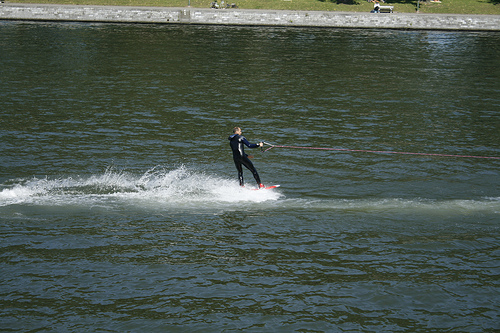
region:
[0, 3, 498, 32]
a wall built along the edge of the water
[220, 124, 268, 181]
man in a black wetsuit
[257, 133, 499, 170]
a red water ski rope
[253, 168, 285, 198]
a red ski board in the water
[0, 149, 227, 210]
the wake of water skiing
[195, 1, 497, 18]
grass on the edge of the water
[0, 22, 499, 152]
ripples in the water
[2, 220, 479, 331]
the sky reflects light on the water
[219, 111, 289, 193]
skiing with one hand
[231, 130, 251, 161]
the front of the wet suit has a shine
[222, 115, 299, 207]
Man wearing a wet suite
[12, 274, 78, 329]
Small ripples in the water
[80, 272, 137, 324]
Small ripples in the water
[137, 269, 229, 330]
Small ripples in the water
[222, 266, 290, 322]
Small ripples in the water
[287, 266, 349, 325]
Small ripples in the water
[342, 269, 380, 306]
Small ripples in the water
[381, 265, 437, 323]
Small ripples in the water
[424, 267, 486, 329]
Small ripples in the water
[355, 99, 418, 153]
Small ripples in the water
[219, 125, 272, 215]
person in a wetsuit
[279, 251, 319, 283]
ripple in the water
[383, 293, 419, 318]
ripple in the water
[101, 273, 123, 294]
ripple in the water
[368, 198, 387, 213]
ripple in the water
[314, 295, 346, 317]
ripple in the water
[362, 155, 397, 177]
ripple in the water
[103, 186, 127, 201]
ripple in the water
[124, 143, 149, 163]
ripple in the water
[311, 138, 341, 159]
ripple in the water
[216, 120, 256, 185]
man is doing a trick in water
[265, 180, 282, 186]
part of ski is coming out of water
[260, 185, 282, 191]
ski is orange in color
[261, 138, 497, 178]
man holding onto line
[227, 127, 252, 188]
man wearing black wet suit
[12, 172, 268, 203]
white caps from the water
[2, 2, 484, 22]
shoreline along side water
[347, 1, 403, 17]
person sitting on bench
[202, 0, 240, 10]
people on the grass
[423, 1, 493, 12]
grass is green along water